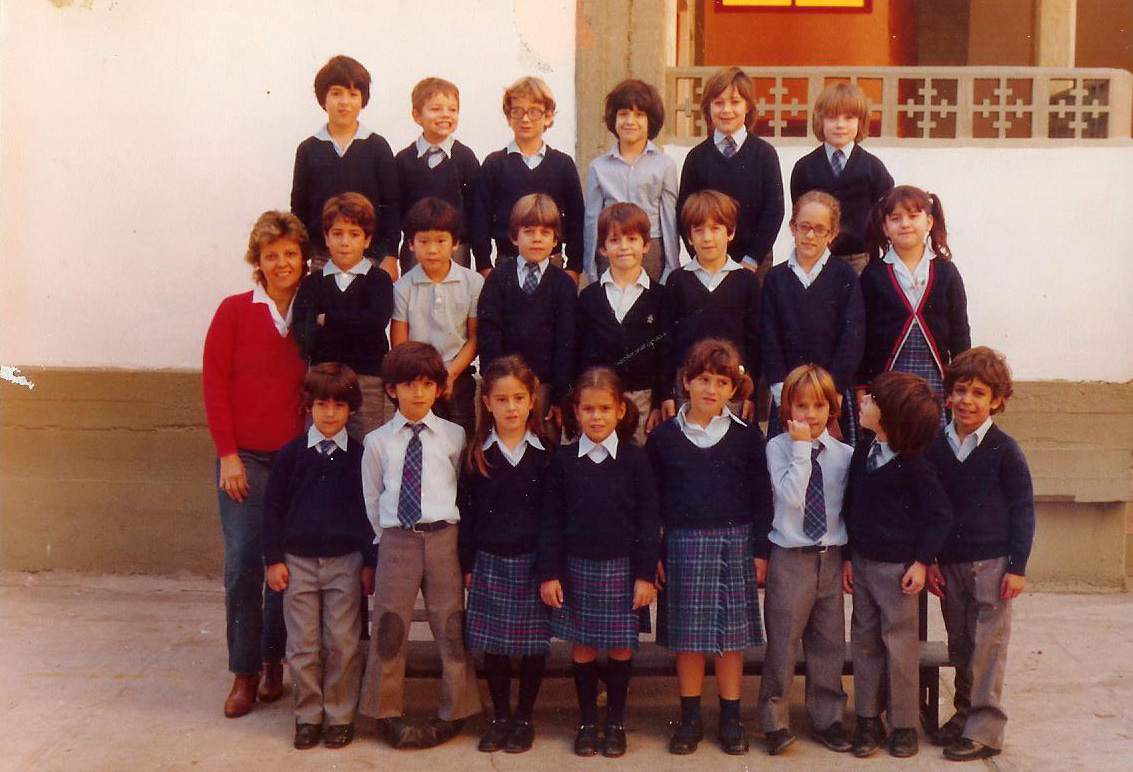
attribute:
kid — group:
[928, 345, 1039, 765]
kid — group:
[857, 360, 947, 766]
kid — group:
[768, 360, 858, 745]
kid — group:
[645, 329, 769, 744]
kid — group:
[551, 376, 657, 745]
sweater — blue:
[847, 434, 939, 574]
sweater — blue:
[461, 431, 548, 563]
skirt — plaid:
[653, 513, 766, 655]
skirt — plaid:
[571, 549, 634, 655]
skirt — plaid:
[464, 552, 551, 655]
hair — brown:
[601, 83, 670, 141]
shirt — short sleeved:
[393, 257, 486, 362]